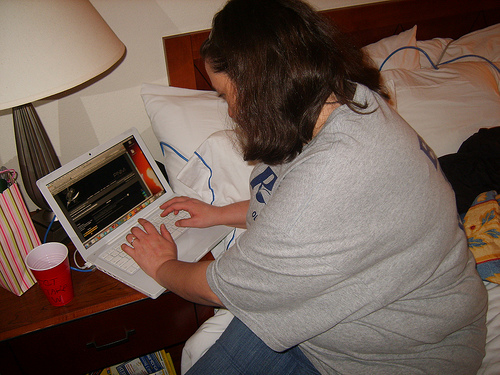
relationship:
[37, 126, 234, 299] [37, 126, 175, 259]
computer has screen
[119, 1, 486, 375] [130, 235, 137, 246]
lady has ring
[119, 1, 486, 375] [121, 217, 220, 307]
lady has hand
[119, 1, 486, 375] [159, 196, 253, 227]
lady has hand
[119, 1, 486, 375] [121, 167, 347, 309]
lady has arm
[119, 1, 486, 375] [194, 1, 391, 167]
lady has hair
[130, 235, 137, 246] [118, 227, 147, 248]
ring on finger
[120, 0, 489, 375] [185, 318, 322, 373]
lady wearing jeans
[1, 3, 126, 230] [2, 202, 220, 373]
lamp on nightstand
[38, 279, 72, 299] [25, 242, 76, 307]
words written on cup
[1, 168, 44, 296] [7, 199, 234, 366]
bag on nightstand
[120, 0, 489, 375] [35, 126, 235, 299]
lady on computer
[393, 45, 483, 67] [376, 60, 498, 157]
cord on pillow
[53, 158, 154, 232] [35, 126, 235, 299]
screen on computer